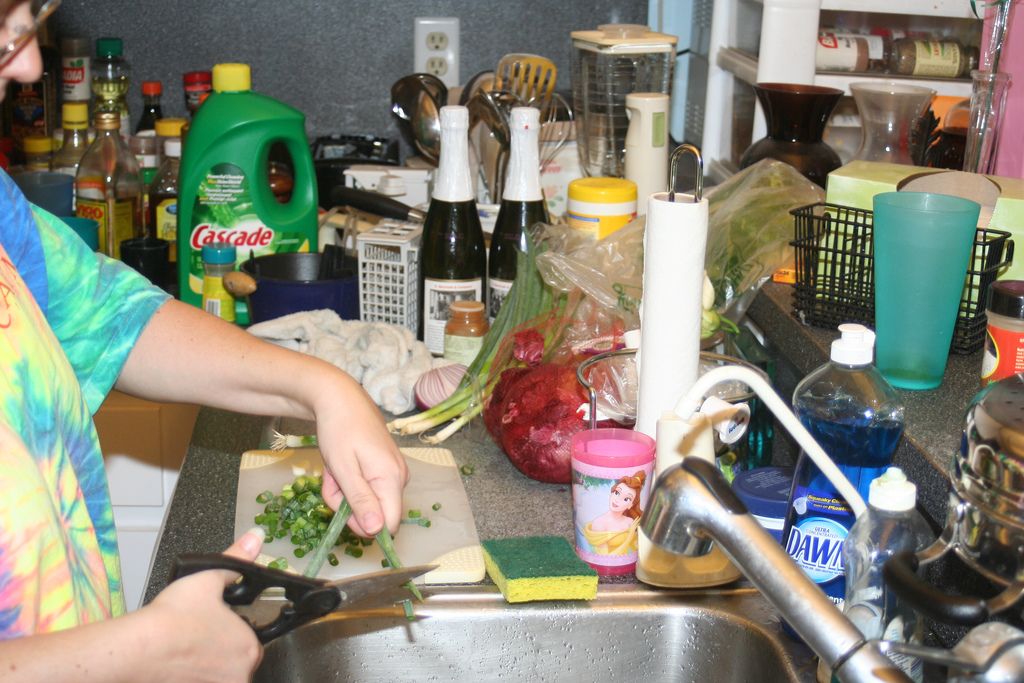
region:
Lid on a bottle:
[199, 55, 261, 91]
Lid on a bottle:
[861, 457, 920, 512]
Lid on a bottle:
[818, 287, 880, 373]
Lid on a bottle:
[171, 62, 210, 97]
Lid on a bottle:
[149, 132, 188, 162]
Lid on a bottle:
[132, 72, 167, 101]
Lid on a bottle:
[89, 31, 131, 58]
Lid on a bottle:
[53, 96, 98, 131]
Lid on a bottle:
[82, 97, 122, 140]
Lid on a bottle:
[13, 123, 53, 159]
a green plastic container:
[163, 56, 341, 370]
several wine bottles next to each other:
[422, 94, 555, 371]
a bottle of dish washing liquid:
[778, 306, 911, 611]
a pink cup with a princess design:
[559, 413, 661, 578]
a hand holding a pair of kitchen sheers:
[142, 515, 453, 680]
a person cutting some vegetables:
[138, 277, 442, 660]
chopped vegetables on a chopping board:
[249, 458, 424, 570]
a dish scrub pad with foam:
[467, 514, 624, 623]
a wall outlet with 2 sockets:
[410, 18, 483, 95]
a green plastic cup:
[869, 168, 980, 406]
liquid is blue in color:
[799, 375, 895, 607]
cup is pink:
[565, 427, 655, 595]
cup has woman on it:
[565, 452, 664, 602]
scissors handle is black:
[185, 527, 357, 663]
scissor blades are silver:
[338, 552, 444, 620]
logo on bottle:
[782, 490, 865, 595]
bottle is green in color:
[186, 54, 324, 296]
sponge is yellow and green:
[479, 534, 607, 620]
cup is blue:
[865, 187, 974, 402]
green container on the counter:
[139, 48, 348, 301]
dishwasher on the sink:
[764, 316, 898, 577]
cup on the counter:
[558, 417, 651, 564]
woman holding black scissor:
[186, 547, 461, 653]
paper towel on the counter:
[640, 141, 716, 449]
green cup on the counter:
[846, 184, 979, 393]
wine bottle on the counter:
[429, 104, 491, 340]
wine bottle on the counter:
[489, 98, 562, 333]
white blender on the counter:
[562, 10, 695, 217]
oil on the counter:
[62, 98, 136, 272]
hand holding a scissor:
[125, 511, 455, 680]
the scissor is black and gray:
[173, 536, 449, 650]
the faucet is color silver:
[607, 441, 903, 680]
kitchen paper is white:
[628, 125, 721, 505]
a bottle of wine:
[416, 91, 499, 374]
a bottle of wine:
[480, 82, 575, 340]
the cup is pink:
[555, 416, 669, 584]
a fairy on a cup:
[575, 470, 653, 559]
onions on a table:
[363, 235, 554, 450]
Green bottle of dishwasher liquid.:
[180, 60, 323, 324]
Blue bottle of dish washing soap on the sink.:
[783, 322, 897, 604]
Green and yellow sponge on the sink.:
[476, 535, 603, 599]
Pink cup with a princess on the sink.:
[563, 429, 640, 575]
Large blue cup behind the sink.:
[869, 193, 981, 386]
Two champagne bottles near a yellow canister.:
[410, 102, 572, 349]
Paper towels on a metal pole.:
[638, 146, 718, 511]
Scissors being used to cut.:
[171, 547, 441, 645]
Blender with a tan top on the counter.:
[568, 26, 679, 224]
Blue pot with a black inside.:
[224, 249, 374, 345]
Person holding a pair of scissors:
[8, 78, 397, 667]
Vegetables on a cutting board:
[255, 464, 414, 562]